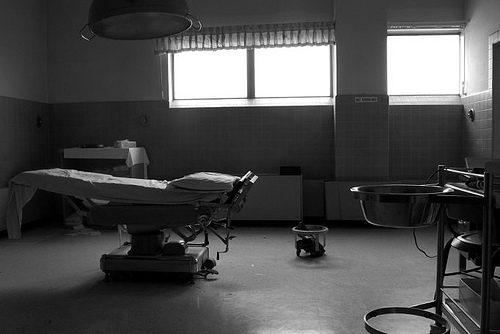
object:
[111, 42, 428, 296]
hospital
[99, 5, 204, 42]
circle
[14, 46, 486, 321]
room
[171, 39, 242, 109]
windows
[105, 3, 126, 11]
light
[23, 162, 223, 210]
bed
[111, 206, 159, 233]
bottom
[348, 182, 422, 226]
sink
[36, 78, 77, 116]
side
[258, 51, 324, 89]
window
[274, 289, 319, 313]
ground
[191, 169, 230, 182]
pillow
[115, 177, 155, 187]
table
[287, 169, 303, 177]
vent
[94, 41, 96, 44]
furnace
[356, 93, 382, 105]
sign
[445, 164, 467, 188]
instruments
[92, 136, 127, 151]
bowl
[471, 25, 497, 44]
doorway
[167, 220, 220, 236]
controls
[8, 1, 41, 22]
ceiling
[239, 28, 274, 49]
curtains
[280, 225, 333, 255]
bin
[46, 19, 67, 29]
wall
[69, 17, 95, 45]
handle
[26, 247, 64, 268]
floor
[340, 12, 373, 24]
tiles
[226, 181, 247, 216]
chair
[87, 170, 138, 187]
sheet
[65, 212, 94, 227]
towels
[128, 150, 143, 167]
cabinet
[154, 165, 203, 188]
supplies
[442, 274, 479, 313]
cage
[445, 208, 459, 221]
corner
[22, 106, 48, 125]
ac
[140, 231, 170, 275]
base